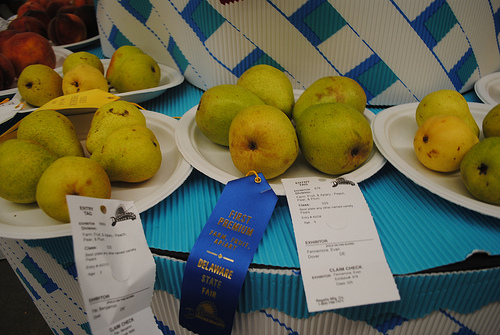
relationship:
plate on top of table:
[173, 87, 388, 197] [63, 39, 499, 273]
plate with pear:
[0, 109, 195, 239] [34, 155, 111, 223]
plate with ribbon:
[173, 87, 388, 197] [177, 171, 279, 334]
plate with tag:
[0, 109, 195, 239] [65, 193, 165, 334]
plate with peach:
[0, 46, 77, 95] [1, 32, 56, 77]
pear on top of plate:
[228, 104, 299, 181] [173, 87, 388, 197]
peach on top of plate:
[1, 32, 56, 77] [0, 46, 77, 95]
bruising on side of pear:
[108, 106, 131, 117] [86, 99, 146, 154]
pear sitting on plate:
[235, 63, 294, 117] [173, 87, 388, 197]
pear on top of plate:
[15, 110, 85, 159] [0, 109, 195, 239]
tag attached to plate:
[281, 176, 403, 313] [173, 87, 388, 197]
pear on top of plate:
[90, 124, 162, 183] [0, 109, 195, 239]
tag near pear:
[65, 193, 165, 334] [34, 155, 111, 223]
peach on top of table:
[6, 15, 48, 38] [63, 39, 499, 273]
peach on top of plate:
[16, 0, 45, 16] [0, 15, 100, 48]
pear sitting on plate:
[415, 89, 480, 140] [369, 99, 499, 218]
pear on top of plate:
[86, 99, 146, 154] [0, 109, 195, 239]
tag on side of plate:
[281, 176, 403, 313] [173, 87, 388, 197]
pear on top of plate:
[110, 53, 162, 94] [17, 58, 184, 111]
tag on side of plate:
[65, 193, 165, 334] [0, 109, 195, 239]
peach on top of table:
[47, 13, 87, 46] [63, 39, 499, 273]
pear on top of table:
[291, 76, 368, 124] [63, 39, 499, 273]